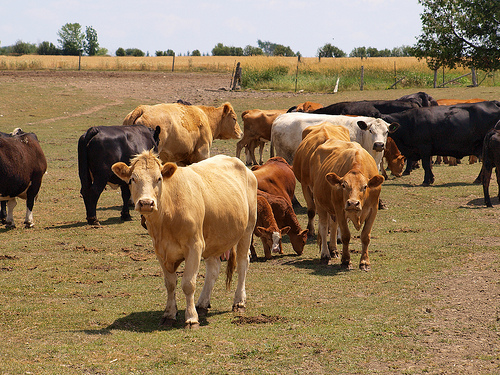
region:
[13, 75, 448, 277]
A lot of cows that are in a pasture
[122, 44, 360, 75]
There is wheat growing in the field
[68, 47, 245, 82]
Fence is made with hedge posts and barbed wire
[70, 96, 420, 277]
There are cows of several colors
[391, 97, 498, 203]
These cows are black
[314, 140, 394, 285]
This is a light brown cow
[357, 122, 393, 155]
This cow is white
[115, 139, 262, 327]
This is a tan colored cow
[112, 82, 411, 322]
Cows like to eat grass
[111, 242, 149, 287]
Manure on the ground from the cows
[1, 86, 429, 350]
herd of cows on a field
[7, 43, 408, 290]
large group of cows together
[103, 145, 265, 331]
brown cow staring forward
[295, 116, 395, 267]
two cows staring forward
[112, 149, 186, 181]
pointy brown ears on cow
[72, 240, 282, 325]
long white legs of cow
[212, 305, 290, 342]
brown pile of dirt on grass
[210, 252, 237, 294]
long brown tail hanging down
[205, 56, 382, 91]
fence in the background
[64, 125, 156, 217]
black cow standing on grass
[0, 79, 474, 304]
large herd of cows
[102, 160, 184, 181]
brown pointy ears of cow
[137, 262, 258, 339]
white legs of cow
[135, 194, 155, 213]
brown and black snout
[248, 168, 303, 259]
cows with their heads down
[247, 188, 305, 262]
cows grazing on grass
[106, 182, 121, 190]
small utters on cows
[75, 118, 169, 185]
black cow standing on grass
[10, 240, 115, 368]
field of grass and dirt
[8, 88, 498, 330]
cows in the pasture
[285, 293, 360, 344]
green grass by cows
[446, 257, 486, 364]
brown patch of grass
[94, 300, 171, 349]
shadow casted on the ground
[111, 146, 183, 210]
face of a cow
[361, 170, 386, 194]
left ear of a cow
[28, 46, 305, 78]
fence in the background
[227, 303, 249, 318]
back hoof of a cow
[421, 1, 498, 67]
green leaves of a tree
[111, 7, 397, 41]
hazy blue sky in the distance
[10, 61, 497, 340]
cows in a field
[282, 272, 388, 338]
grass of a field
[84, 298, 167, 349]
shadow casted on the grass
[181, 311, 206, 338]
front hoof of a cow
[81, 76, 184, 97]
dirt patch on the grass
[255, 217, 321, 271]
cows grazing in the grass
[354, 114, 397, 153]
face of a white cow